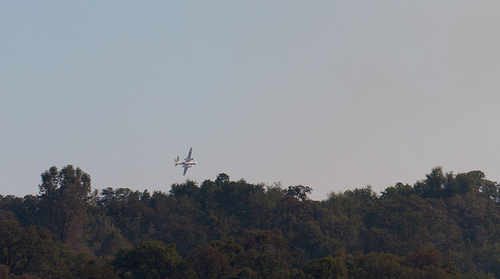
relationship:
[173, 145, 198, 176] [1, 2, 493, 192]
plane in sky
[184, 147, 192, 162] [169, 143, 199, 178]
left wing on plane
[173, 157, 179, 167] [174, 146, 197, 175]
tail on plane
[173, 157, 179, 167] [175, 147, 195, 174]
tail on plane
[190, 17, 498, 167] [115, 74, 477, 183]
clouds are in sky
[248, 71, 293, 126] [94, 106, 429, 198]
clouds are in sky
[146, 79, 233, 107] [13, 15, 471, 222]
cloud are in sky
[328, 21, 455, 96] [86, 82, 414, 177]
clouds are in sky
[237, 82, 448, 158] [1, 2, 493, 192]
clouds are in sky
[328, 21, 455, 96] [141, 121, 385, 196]
clouds are in sky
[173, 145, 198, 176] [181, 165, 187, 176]
plane has right wing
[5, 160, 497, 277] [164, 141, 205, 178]
trees under airplane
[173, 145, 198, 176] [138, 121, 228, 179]
plane on air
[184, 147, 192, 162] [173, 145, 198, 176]
left wing of plane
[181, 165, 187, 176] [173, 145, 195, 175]
right wing of plane